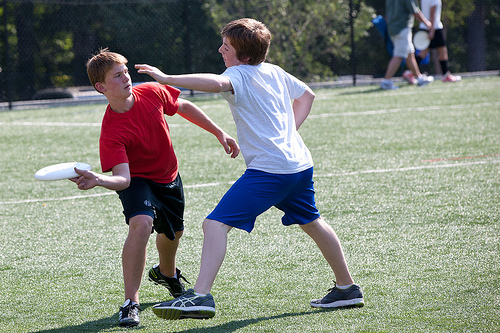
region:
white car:
[207, 165, 337, 235]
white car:
[201, 128, 363, 270]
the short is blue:
[234, 205, 243, 220]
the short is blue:
[229, 199, 235, 214]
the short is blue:
[239, 197, 247, 219]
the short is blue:
[230, 197, 247, 219]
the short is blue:
[237, 213, 243, 214]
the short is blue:
[238, 209, 250, 219]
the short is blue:
[242, 208, 254, 225]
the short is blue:
[242, 213, 247, 223]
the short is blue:
[243, 205, 251, 215]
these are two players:
[64, 8, 313, 304]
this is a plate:
[36, 155, 91, 200]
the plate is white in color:
[33, 158, 85, 186]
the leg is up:
[176, 222, 240, 315]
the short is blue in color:
[250, 189, 295, 215]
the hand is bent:
[87, 126, 144, 201]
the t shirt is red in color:
[134, 118, 164, 163]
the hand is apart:
[129, 58, 228, 89]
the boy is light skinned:
[211, 239, 224, 251]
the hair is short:
[241, 25, 262, 47]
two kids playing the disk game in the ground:
[53, 3, 409, 322]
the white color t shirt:
[222, 61, 322, 171]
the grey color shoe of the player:
[304, 278, 373, 316]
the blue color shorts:
[208, 158, 331, 234]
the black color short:
[110, 163, 198, 236]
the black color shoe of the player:
[97, 286, 139, 331]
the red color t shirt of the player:
[84, 93, 196, 184]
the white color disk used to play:
[24, 147, 99, 185]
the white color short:
[383, 13, 420, 67]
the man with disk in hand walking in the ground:
[413, 6, 466, 85]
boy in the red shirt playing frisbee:
[67, 48, 234, 329]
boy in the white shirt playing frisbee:
[135, 20, 365, 310]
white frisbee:
[35, 160, 90, 175]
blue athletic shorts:
[205, 166, 315, 223]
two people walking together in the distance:
[375, 0, 460, 82]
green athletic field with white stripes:
[0, 81, 490, 326]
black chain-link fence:
[0, 1, 497, 106]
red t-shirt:
[95, 81, 180, 176]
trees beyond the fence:
[1, 0, 491, 95]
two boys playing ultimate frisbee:
[35, 15, 362, 320]